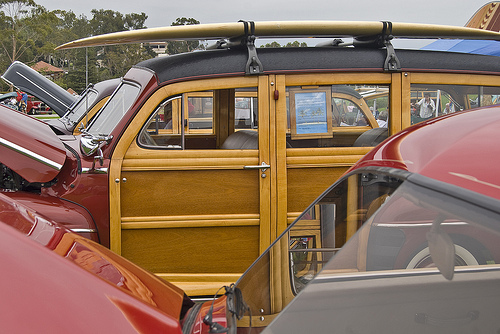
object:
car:
[0, 60, 121, 135]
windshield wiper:
[200, 285, 231, 334]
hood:
[0, 190, 196, 334]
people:
[20, 90, 27, 112]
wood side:
[120, 165, 261, 216]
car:
[0, 19, 500, 296]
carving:
[462, 0, 500, 33]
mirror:
[94, 147, 104, 159]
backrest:
[353, 127, 388, 147]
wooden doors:
[107, 73, 277, 296]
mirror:
[424, 213, 457, 282]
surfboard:
[53, 18, 500, 50]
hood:
[0, 60, 77, 118]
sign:
[295, 92, 329, 134]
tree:
[0, 0, 80, 95]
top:
[120, 46, 500, 83]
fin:
[464, 0, 500, 32]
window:
[284, 84, 389, 147]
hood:
[0, 103, 66, 183]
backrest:
[219, 130, 258, 149]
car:
[0, 104, 500, 334]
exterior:
[0, 19, 500, 296]